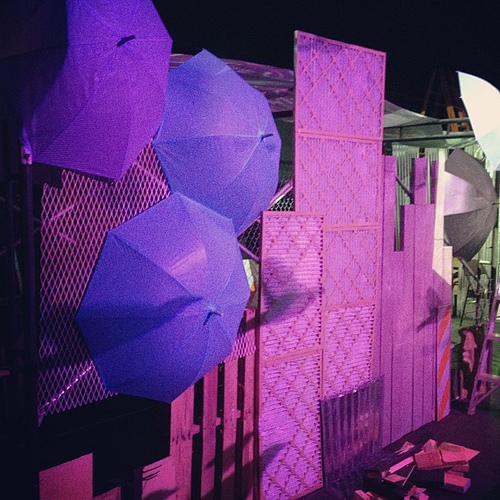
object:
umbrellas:
[22, 3, 287, 413]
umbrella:
[455, 70, 498, 179]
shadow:
[237, 257, 323, 335]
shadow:
[414, 285, 455, 332]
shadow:
[41, 292, 204, 369]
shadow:
[199, 431, 291, 498]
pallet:
[248, 204, 327, 498]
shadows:
[140, 461, 203, 499]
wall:
[0, 90, 455, 498]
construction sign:
[434, 304, 452, 420]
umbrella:
[147, 45, 288, 246]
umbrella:
[71, 188, 253, 407]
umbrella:
[436, 140, 498, 268]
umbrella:
[448, 59, 498, 182]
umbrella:
[0, 0, 175, 185]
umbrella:
[101, 216, 263, 346]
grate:
[20, 135, 189, 423]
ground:
[239, 411, 493, 499]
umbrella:
[156, 49, 284, 231]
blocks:
[353, 440, 480, 499]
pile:
[440, 469, 472, 497]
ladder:
[466, 272, 499, 418]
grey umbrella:
[455, 69, 498, 172]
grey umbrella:
[442, 147, 496, 264]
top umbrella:
[76, 203, 254, 406]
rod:
[211, 309, 223, 317]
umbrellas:
[56, 36, 282, 411]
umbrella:
[446, 150, 499, 262]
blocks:
[354, 435, 481, 497]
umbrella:
[75, 191, 248, 398]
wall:
[296, 31, 390, 387]